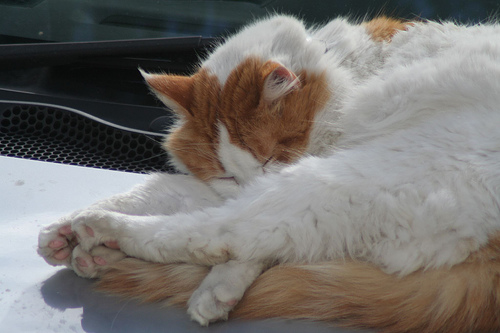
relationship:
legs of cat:
[73, 168, 356, 270] [33, 7, 500, 330]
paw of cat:
[36, 218, 79, 269] [33, 7, 500, 330]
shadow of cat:
[40, 257, 385, 332] [33, 7, 500, 330]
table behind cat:
[1, 144, 499, 332] [33, 7, 500, 330]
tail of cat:
[93, 247, 500, 331] [33, 7, 500, 330]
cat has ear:
[33, 7, 500, 330] [135, 66, 194, 114]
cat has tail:
[33, 7, 500, 330] [93, 247, 500, 331]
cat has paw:
[33, 7, 500, 330] [36, 218, 79, 269]